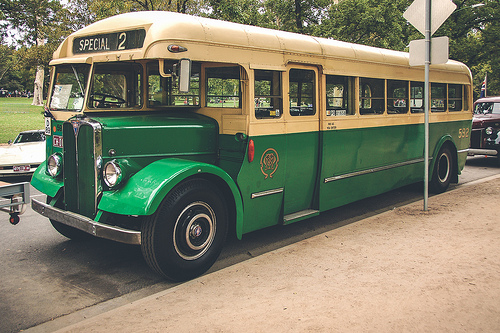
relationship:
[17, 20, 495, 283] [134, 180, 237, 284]
bus has blackwheels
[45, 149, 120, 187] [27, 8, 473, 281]
headlights on bus